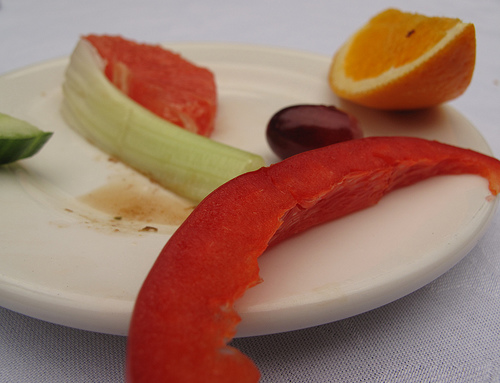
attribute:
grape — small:
[270, 107, 365, 143]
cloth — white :
[268, 5, 498, 381]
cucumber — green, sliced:
[1, 103, 55, 172]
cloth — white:
[0, 0, 498, 381]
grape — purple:
[267, 101, 367, 161]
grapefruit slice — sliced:
[122, 136, 499, 380]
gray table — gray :
[0, 0, 499, 380]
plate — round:
[38, 200, 323, 338]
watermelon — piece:
[1, 115, 60, 170]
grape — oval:
[249, 75, 406, 172]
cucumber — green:
[0, 111, 55, 168]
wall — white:
[18, 18, 55, 50]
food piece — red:
[141, 141, 498, 381]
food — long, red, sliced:
[123, 134, 498, 381]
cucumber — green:
[2, 110, 51, 164]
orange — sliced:
[328, 7, 475, 112]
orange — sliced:
[322, 20, 453, 88]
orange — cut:
[329, 12, 489, 120]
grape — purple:
[265, 99, 326, 146]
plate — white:
[2, 41, 495, 337]